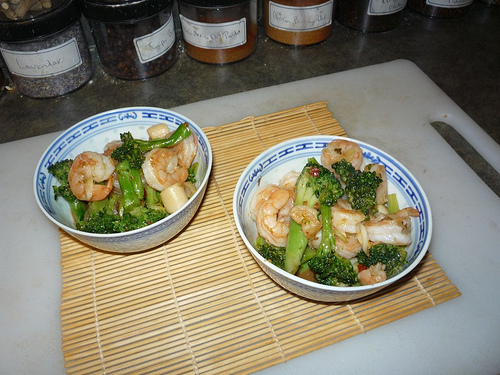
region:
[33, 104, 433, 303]
two white bowls of food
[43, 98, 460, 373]
a small bamboo mat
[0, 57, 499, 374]
a white plastic cutting board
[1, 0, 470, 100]
round containers of spices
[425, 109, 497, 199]
handle on the cutting board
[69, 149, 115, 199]
shrimp in the dish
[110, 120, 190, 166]
broccoli in the dish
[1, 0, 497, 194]
a granite counter top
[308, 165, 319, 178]
a piece of pepper in the food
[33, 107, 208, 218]
blue design in the bowl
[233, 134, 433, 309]
a bowl of shrimp and broccolli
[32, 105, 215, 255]
another bowl of shrimp and broccolli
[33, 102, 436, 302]
two bowls of shrimp and broccoli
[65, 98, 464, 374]
a bamboo matt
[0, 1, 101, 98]
a jar of Lavender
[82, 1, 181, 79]
a jar of edibles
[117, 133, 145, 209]
a piece of broccoli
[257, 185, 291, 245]
a big deveined shrimp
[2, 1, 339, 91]
four jars of spices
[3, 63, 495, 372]
a large white cutting board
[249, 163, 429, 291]
There is shrimp and broccoli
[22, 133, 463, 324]
There are two bowls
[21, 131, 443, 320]
The bowls are on a bamboo mat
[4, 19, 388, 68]
There are spices in the back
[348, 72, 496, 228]
This is a cutting board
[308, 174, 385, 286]
The broccoli is green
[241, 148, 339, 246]
The bowls are white and blue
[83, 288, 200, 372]
The mat is brown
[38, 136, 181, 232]
The shrimp is sea-food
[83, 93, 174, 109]
The counter is dark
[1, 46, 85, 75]
a label on a jar of lavender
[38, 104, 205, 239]
a bowl of brocolli and shrimp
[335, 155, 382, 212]
a broccolli floret in a bowl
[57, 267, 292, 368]
part of a bamboo placemat on a table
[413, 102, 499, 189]
the cut out handle of a cutting board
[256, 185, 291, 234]
a piece of shrimp in a bowl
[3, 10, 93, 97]
a jar of lavender with a label on it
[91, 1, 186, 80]
a jar with a label sitting on the table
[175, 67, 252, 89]
a section of a table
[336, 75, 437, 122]
a white cutting board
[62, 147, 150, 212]
Shrimp and broccoli in a bowl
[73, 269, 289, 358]
A bamboo placemat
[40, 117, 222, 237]
A white bowl with blue designs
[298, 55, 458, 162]
A large white cutting board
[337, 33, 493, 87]
A marbled countertop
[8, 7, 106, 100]
Lavender in a jar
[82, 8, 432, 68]
Glass jars full of spices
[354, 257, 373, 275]
A red pepper in with the broccoli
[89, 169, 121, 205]
An orange shrimp tailed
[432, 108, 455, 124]
A dirty spot on a cutting board